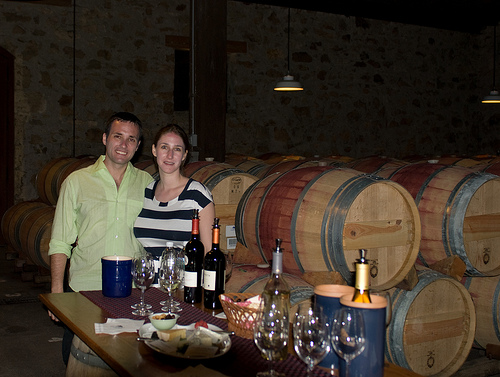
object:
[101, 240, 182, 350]
vase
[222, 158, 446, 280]
wooden barrels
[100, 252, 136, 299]
cup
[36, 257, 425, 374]
table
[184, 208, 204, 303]
bottle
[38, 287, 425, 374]
table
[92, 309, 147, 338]
two birds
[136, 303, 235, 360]
plate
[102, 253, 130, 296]
vase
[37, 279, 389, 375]
table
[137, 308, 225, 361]
plate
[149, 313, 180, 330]
bowl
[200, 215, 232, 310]
wine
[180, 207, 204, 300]
wine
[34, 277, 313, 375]
table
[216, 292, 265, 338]
basket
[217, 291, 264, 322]
napkin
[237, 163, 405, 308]
wooden barrel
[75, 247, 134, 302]
vase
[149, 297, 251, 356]
flowers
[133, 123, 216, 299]
woman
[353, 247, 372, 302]
bottle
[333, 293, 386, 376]
chiller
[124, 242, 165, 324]
glass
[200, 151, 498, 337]
barrels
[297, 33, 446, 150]
stone wall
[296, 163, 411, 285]
keg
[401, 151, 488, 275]
keg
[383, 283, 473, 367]
keg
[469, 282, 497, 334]
keg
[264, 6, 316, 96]
light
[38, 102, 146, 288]
man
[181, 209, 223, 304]
wine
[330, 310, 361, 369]
glasses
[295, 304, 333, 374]
glasses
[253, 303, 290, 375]
glasses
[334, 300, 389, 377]
blue pot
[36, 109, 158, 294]
man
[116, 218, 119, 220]
button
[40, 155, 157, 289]
shirt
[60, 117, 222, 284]
people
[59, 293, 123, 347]
table